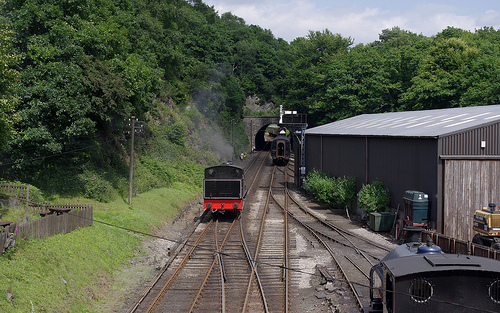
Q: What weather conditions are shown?
A: It is cloudy.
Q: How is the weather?
A: It is cloudy.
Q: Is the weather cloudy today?
A: Yes, it is cloudy.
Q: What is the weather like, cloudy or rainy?
A: It is cloudy.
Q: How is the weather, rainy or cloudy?
A: It is cloudy.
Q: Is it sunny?
A: No, it is cloudy.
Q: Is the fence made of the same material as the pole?
A: Yes, both the fence and the pole are made of wood.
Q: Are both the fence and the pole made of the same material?
A: Yes, both the fence and the pole are made of wood.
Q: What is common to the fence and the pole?
A: The material, both the fence and the pole are wooden.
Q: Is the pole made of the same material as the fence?
A: Yes, both the pole and the fence are made of wood.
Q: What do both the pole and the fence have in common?
A: The material, both the pole and the fence are wooden.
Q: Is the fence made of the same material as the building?
A: No, the fence is made of wood and the building is made of metal.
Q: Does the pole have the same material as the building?
A: No, the pole is made of wood and the building is made of metal.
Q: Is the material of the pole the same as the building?
A: No, the pole is made of wood and the building is made of metal.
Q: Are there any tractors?
A: Yes, there is a tractor.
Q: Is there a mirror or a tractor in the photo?
A: Yes, there is a tractor.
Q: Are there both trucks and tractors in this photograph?
A: No, there is a tractor but no trucks.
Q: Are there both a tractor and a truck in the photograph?
A: No, there is a tractor but no trucks.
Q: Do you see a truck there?
A: No, there are no trucks.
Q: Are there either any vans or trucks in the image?
A: No, there are no trucks or vans.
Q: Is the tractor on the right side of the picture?
A: Yes, the tractor is on the right of the image.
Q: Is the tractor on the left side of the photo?
A: No, the tractor is on the right of the image.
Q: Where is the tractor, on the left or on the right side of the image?
A: The tractor is on the right of the image.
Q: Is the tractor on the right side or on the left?
A: The tractor is on the right of the image.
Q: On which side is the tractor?
A: The tractor is on the right of the image.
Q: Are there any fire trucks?
A: No, there are no fire trucks.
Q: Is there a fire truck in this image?
A: No, there are no fire trucks.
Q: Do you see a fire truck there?
A: No, there are no fire trucks.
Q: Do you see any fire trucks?
A: No, there are no fire trucks.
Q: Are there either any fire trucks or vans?
A: No, there are no fire trucks or vans.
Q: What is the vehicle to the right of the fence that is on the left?
A: The vehicle is a car.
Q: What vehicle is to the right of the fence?
A: The vehicle is a car.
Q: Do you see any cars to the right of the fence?
A: Yes, there is a car to the right of the fence.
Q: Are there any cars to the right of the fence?
A: Yes, there is a car to the right of the fence.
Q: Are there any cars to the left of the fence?
A: No, the car is to the right of the fence.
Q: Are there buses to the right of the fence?
A: No, there is a car to the right of the fence.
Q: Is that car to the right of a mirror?
A: No, the car is to the right of a fence.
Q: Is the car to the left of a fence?
A: No, the car is to the right of a fence.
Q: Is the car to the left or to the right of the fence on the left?
A: The car is to the right of the fence.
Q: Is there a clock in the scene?
A: No, there are no clocks.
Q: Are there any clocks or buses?
A: No, there are no clocks or buses.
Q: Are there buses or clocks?
A: No, there are no clocks or buses.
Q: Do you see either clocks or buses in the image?
A: No, there are no clocks or buses.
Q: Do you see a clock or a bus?
A: No, there are no clocks or buses.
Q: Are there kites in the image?
A: No, there are no kites.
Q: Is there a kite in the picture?
A: No, there are no kites.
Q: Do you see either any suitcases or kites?
A: No, there are no kites or suitcases.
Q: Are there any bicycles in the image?
A: No, there are no bicycles.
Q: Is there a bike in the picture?
A: No, there are no bikes.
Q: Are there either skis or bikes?
A: No, there are no bikes or skis.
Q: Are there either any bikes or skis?
A: No, there are no bikes or skis.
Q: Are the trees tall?
A: Yes, the trees are tall.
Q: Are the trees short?
A: No, the trees are tall.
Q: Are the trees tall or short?
A: The trees are tall.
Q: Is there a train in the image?
A: Yes, there is a train.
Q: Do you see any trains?
A: Yes, there is a train.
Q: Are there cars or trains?
A: Yes, there is a train.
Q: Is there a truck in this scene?
A: No, there are no trucks.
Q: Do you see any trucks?
A: No, there are no trucks.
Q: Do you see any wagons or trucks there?
A: No, there are no trucks or wagons.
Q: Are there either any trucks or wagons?
A: No, there are no trucks or wagons.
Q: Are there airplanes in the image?
A: No, there are no airplanes.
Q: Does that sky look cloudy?
A: Yes, the sky is cloudy.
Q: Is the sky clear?
A: No, the sky is cloudy.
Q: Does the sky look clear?
A: No, the sky is cloudy.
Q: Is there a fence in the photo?
A: Yes, there is a fence.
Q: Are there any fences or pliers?
A: Yes, there is a fence.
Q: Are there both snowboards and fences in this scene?
A: No, there is a fence but no snowboards.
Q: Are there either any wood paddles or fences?
A: Yes, there is a wood fence.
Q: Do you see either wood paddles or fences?
A: Yes, there is a wood fence.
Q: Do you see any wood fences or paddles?
A: Yes, there is a wood fence.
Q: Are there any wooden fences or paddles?
A: Yes, there is a wood fence.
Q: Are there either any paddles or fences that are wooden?
A: Yes, the fence is wooden.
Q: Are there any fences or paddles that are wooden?
A: Yes, the fence is wooden.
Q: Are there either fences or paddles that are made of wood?
A: Yes, the fence is made of wood.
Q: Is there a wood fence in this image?
A: Yes, there is a wood fence.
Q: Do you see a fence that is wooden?
A: Yes, there is a wood fence.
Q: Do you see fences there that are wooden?
A: Yes, there is a fence that is wooden.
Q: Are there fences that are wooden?
A: Yes, there is a fence that is wooden.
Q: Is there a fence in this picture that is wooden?
A: Yes, there is a fence that is wooden.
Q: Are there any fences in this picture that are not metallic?
A: Yes, there is a wooden fence.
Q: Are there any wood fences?
A: Yes, there is a fence that is made of wood.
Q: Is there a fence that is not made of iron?
A: Yes, there is a fence that is made of wood.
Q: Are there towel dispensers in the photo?
A: No, there are no towel dispensers.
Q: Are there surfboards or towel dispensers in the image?
A: No, there are no towel dispensers or surfboards.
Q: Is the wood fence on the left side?
A: Yes, the fence is on the left of the image.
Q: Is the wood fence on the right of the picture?
A: No, the fence is on the left of the image.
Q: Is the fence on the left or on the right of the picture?
A: The fence is on the left of the image.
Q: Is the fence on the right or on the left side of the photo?
A: The fence is on the left of the image.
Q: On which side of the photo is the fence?
A: The fence is on the left of the image.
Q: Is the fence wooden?
A: Yes, the fence is wooden.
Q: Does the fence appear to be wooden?
A: Yes, the fence is wooden.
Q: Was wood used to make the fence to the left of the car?
A: Yes, the fence is made of wood.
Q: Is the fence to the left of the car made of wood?
A: Yes, the fence is made of wood.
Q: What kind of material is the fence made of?
A: The fence is made of wood.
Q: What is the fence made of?
A: The fence is made of wood.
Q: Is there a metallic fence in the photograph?
A: No, there is a fence but it is wooden.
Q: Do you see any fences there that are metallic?
A: No, there is a fence but it is wooden.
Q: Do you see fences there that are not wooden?
A: No, there is a fence but it is wooden.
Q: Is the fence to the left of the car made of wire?
A: No, the fence is made of wood.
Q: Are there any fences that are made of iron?
A: No, there is a fence but it is made of wood.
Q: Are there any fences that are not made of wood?
A: No, there is a fence but it is made of wood.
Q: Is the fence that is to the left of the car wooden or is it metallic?
A: The fence is wooden.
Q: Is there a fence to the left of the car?
A: Yes, there is a fence to the left of the car.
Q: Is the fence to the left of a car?
A: Yes, the fence is to the left of a car.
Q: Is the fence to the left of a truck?
A: No, the fence is to the left of a car.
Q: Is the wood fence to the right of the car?
A: No, the fence is to the left of the car.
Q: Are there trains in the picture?
A: Yes, there is a train.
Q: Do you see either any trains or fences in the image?
A: Yes, there is a train.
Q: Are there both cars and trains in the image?
A: Yes, there are both a train and a car.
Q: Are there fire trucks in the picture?
A: No, there are no fire trucks.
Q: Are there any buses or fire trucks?
A: No, there are no fire trucks or buses.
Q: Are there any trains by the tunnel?
A: Yes, there is a train by the tunnel.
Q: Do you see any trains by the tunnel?
A: Yes, there is a train by the tunnel.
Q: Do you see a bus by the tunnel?
A: No, there is a train by the tunnel.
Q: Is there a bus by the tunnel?
A: No, there is a train by the tunnel.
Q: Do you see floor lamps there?
A: No, there are no floor lamps.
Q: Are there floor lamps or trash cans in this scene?
A: No, there are no floor lamps or trash cans.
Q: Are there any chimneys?
A: No, there are no chimneys.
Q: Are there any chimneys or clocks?
A: No, there are no chimneys or clocks.